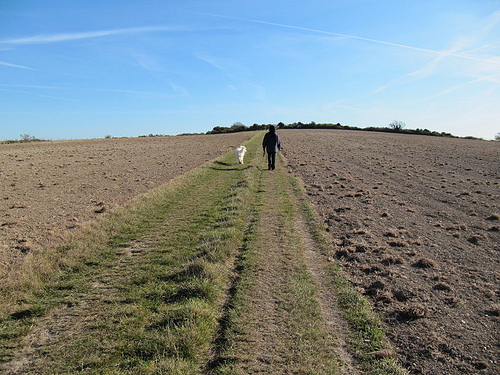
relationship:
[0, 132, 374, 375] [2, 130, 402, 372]
road on grass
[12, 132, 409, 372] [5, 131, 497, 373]
grass strip in middle of field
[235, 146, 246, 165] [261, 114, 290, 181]
animal walking beside man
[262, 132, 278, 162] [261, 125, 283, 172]
outfit of man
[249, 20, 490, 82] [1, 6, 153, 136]
contrail in sky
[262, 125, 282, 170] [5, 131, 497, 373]
man in a field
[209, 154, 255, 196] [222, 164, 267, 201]
person's shadow on ground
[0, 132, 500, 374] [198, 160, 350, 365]
grass strip made of dirt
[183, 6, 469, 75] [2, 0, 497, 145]
lines in sky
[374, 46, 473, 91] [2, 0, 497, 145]
lines in sky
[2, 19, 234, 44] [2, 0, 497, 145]
lines in sky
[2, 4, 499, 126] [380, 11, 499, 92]
sky has cloud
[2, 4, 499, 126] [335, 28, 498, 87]
sky has cloud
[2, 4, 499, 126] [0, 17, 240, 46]
sky has cloud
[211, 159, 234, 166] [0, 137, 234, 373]
shadow on ground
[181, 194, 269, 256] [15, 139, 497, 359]
grass on field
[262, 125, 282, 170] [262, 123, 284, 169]
man wearing black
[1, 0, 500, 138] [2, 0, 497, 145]
cloud hanging in sky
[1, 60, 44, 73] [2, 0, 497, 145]
cloud hanging in sky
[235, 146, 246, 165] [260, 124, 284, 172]
animal walking next to person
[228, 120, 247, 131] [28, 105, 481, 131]
tree seen on horizon line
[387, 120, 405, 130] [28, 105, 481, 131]
tree seen on horizon line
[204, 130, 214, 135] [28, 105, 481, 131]
shrub seen on horizon line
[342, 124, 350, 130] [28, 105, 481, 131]
shrub seen on horizon line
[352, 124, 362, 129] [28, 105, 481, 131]
shrub seen on horizon line